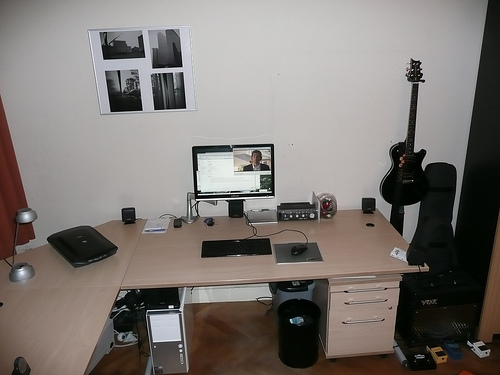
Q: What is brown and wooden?
A: A desk.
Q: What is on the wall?
A: A guitar.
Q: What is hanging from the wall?
A: A painting.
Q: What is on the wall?
A: A guitar.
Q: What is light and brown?
A: A desk.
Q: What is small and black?
A: A guitar.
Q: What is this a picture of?
A: An office.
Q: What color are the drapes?
A: Red.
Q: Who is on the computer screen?
A: A person.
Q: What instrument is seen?
A: A guitar.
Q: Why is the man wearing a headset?
A: He's on a call.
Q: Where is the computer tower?
A: Under the desk.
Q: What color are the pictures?
A: Black and white.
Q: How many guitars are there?
A: One.